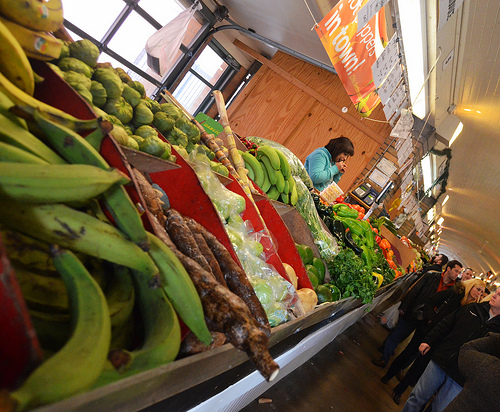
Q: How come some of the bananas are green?
A: They are not yet ripe.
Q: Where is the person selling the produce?
A: Behind the bins.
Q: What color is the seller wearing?
A: Blue.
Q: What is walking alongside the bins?
A: Shoppers.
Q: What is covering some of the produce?
A: Plastic.